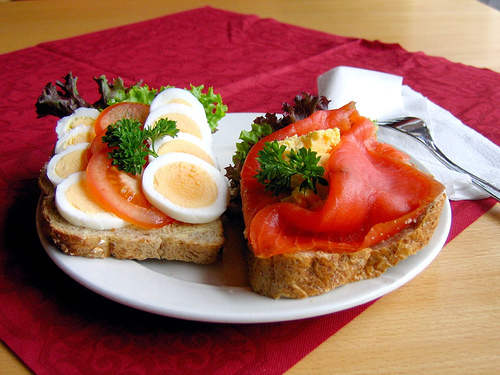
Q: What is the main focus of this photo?
A: A plate of food.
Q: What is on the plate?
A: An open sandwich.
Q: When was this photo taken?
A: Before a meal time.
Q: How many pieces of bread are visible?
A: Two.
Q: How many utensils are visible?
A: One.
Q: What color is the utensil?
A: Silver.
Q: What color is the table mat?
A: Red.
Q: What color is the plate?
A: White.